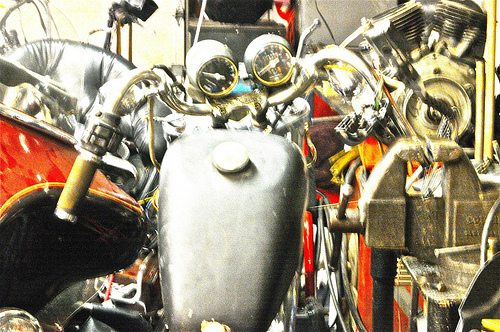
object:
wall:
[295, 0, 398, 45]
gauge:
[184, 38, 239, 93]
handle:
[57, 153, 97, 223]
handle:
[322, 181, 363, 273]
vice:
[328, 126, 499, 318]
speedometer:
[248, 43, 294, 84]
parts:
[104, 1, 172, 53]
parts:
[1, 87, 131, 316]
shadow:
[233, 164, 253, 176]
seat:
[153, 303, 258, 332]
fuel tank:
[151, 100, 301, 327]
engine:
[369, 0, 488, 143]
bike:
[0, 0, 500, 331]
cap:
[213, 142, 248, 174]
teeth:
[394, 141, 462, 163]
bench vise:
[357, 137, 497, 251]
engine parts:
[339, 0, 498, 150]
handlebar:
[371, 88, 426, 148]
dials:
[197, 58, 238, 96]